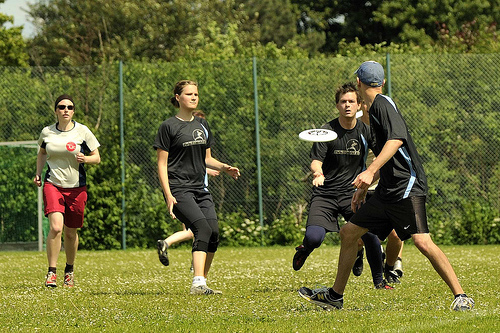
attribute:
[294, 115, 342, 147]
frisbee — white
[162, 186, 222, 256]
pants — black, running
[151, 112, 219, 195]
shirt — black, te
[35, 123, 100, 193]
shirt — white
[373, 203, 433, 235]
shorts — Nike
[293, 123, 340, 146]
frisbee — white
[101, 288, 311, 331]
grasses — green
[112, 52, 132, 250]
poles — blue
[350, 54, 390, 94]
cap — blue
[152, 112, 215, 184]
shirt — black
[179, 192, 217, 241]
short — black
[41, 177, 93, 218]
shorts — red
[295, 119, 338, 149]
frisbee — white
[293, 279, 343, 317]
sneaker — dark blue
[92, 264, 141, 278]
flowers — clover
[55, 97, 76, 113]
sunglasses — rectangular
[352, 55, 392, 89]
cap — blue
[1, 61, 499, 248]
fence — green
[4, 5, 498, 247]
bushes — green, tall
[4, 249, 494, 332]
grass — yellowish green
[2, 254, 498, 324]
flowers — small, white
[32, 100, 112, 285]
woman — young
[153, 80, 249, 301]
woman — young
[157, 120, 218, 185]
shirt — black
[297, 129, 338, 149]
frisbee — white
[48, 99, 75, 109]
sunglasses — black 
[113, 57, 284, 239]
poles — green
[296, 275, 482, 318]
laces — some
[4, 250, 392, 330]
ground — grassy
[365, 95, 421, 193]
shirt — black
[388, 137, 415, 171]
stripe — blue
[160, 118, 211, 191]
shirt — black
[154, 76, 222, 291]
woman — one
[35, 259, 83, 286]
sneakers — red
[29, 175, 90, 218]
shorts — red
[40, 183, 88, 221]
shorts — red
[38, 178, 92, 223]
shorts — red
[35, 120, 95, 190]
shirt — white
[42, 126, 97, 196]
shirt — white, black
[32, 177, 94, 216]
shorts — red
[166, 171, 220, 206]
shorts — black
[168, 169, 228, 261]
leggings — black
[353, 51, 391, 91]
cap — blue, ball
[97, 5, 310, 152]
leaves — green